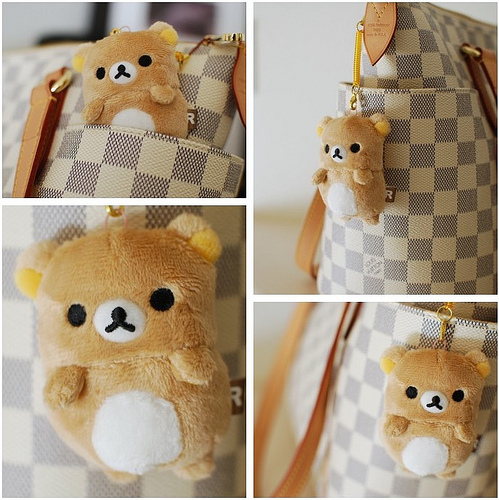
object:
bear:
[69, 17, 192, 141]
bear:
[306, 108, 397, 229]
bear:
[11, 207, 237, 491]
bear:
[374, 341, 495, 486]